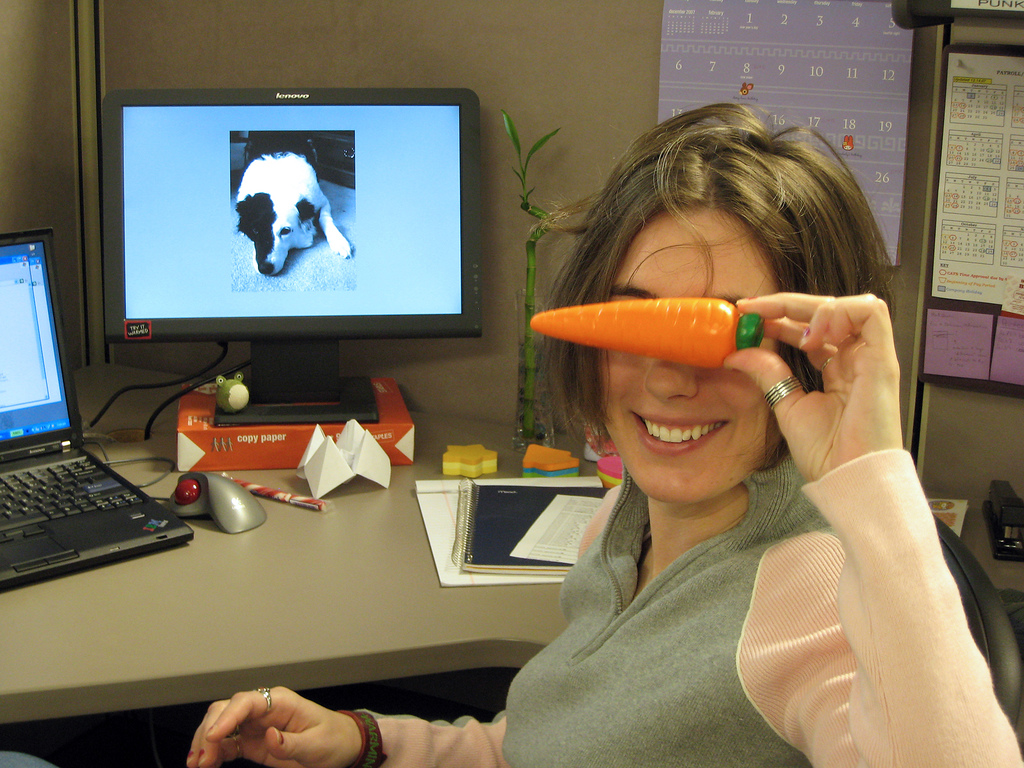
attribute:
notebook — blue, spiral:
[454, 476, 604, 580]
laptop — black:
[1, 227, 200, 595]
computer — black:
[3, 230, 192, 602]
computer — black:
[94, 81, 484, 464]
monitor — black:
[100, 96, 477, 330]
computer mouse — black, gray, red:
[199, 467, 266, 539]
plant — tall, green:
[493, 113, 565, 448]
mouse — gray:
[178, 463, 261, 535]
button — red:
[150, 452, 207, 498]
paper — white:
[272, 404, 452, 521]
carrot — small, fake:
[499, 281, 787, 402]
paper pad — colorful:
[441, 430, 509, 474]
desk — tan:
[9, 372, 1021, 736]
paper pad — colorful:
[519, 434, 582, 482]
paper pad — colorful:
[590, 440, 634, 495]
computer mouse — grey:
[173, 458, 269, 551]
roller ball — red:
[166, 484, 203, 506]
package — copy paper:
[158, 369, 429, 491]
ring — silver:
[758, 365, 802, 413]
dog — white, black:
[222, 146, 348, 283]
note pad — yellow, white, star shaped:
[430, 432, 511, 480]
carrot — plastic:
[512, 280, 761, 373]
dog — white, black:
[214, 153, 377, 287]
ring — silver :
[765, 363, 809, 415]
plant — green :
[454, 93, 584, 467]